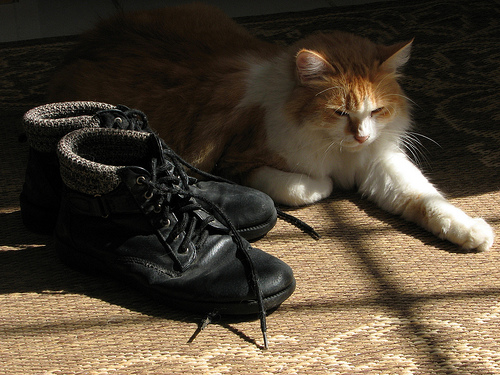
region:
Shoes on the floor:
[21, 99, 301, 319]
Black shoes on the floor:
[15, 91, 321, 346]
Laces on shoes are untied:
[110, 91, 325, 346]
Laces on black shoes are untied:
[23, 94, 300, 319]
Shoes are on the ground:
[18, 92, 323, 351]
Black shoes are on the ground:
[19, 97, 302, 319]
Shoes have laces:
[117, 98, 325, 353]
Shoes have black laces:
[107, 101, 320, 347]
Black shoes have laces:
[102, 98, 322, 351]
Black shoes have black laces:
[100, 101, 325, 348]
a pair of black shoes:
[17, 89, 327, 349]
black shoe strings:
[134, 110, 321, 349]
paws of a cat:
[292, 181, 494, 256]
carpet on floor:
[3, 6, 498, 374]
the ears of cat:
[322, 101, 388, 118]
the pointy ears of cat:
[291, 38, 415, 79]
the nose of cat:
[348, 126, 373, 145]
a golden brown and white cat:
[51, 6, 497, 258]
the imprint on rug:
[38, 306, 497, 374]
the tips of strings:
[182, 224, 321, 349]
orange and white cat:
[50, 4, 494, 267]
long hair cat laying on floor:
[41, 4, 493, 259]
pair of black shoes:
[15, 88, 303, 330]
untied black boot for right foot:
[51, 126, 307, 335]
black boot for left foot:
[19, 97, 281, 242]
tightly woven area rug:
[11, 11, 495, 373]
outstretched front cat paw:
[351, 138, 498, 258]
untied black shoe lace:
[122, 143, 281, 353]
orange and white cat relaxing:
[42, 5, 499, 268]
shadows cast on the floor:
[5, 190, 498, 373]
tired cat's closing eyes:
[323, 101, 390, 122]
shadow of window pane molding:
[308, 208, 443, 370]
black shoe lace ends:
[181, 314, 276, 350]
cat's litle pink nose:
[349, 132, 373, 146]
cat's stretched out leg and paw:
[359, 156, 489, 248]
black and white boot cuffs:
[24, 93, 164, 175]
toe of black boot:
[202, 238, 296, 323]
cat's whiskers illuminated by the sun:
[386, 121, 433, 162]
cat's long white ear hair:
[307, 51, 322, 78]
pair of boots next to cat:
[24, 96, 296, 319]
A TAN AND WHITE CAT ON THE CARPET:
[41, 2, 498, 254]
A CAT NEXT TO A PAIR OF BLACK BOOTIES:
[17, 22, 497, 342]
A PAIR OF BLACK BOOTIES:
[14, 97, 323, 355]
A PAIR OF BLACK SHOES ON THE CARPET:
[10, 97, 370, 372]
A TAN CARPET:
[284, 225, 498, 372]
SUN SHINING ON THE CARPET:
[294, 255, 491, 373]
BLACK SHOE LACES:
[132, 159, 272, 351]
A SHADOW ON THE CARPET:
[296, 215, 486, 368]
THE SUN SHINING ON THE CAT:
[42, 0, 498, 255]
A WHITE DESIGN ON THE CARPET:
[163, 297, 496, 371]